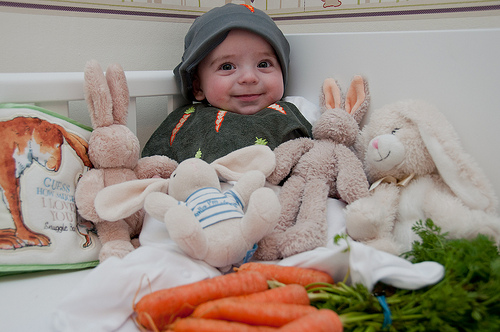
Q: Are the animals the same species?
A: Yes, all the animals are bunnies.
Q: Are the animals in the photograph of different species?
A: No, all the animals are bunnies.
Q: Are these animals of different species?
A: No, all the animals are bunnies.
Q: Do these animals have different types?
A: No, all the animals are bunnies.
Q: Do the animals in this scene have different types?
A: No, all the animals are bunnies.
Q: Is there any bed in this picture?
A: Yes, there is a bed.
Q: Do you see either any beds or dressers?
A: Yes, there is a bed.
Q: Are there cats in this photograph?
A: No, there are no cats.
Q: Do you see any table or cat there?
A: No, there are no cats or tables.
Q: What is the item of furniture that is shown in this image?
A: The piece of furniture is a bed.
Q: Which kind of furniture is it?
A: The piece of furniture is a bed.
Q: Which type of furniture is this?
A: This is a bed.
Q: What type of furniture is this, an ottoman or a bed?
A: This is a bed.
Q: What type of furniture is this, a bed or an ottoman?
A: This is a bed.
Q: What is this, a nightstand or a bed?
A: This is a bed.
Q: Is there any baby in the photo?
A: Yes, there is a baby.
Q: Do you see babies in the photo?
A: Yes, there is a baby.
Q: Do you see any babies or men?
A: Yes, there is a baby.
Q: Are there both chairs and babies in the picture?
A: No, there is a baby but no chairs.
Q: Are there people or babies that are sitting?
A: Yes, the baby is sitting.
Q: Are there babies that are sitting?
A: Yes, there is a baby that is sitting.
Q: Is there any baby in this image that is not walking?
A: Yes, there is a baby that is sitting.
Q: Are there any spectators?
A: No, there are no spectators.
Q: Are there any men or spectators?
A: No, there are no spectators or men.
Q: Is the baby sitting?
A: Yes, the baby is sitting.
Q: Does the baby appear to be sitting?
A: Yes, the baby is sitting.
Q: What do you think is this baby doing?
A: The baby is sitting.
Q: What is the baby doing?
A: The baby is sitting.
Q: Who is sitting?
A: The baby is sitting.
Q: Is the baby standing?
A: No, the baby is sitting.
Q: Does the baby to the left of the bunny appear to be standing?
A: No, the baby is sitting.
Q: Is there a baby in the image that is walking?
A: No, there is a baby but he is sitting.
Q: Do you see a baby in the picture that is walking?
A: No, there is a baby but he is sitting.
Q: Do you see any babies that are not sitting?
A: No, there is a baby but he is sitting.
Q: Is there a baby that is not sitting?
A: No, there is a baby but he is sitting.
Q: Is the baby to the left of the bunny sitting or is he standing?
A: The baby is sitting.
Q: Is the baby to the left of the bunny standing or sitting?
A: The baby is sitting.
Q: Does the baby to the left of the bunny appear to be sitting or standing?
A: The baby is sitting.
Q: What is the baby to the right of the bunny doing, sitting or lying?
A: The baby is sitting.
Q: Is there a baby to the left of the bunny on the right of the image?
A: Yes, there is a baby to the left of the bunny.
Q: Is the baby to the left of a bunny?
A: Yes, the baby is to the left of a bunny.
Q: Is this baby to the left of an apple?
A: No, the baby is to the left of a bunny.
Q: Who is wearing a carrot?
A: The baby is wearing a carrot.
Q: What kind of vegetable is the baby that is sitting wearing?
A: The baby is wearing a carrot.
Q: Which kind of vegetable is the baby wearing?
A: The baby is wearing a carrot.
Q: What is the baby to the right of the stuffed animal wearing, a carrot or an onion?
A: The baby is wearing a carrot.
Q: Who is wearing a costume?
A: The baby is wearing a costume.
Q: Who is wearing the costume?
A: The baby is wearing a costume.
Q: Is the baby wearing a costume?
A: Yes, the baby is wearing a costume.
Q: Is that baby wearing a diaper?
A: No, the baby is wearing a costume.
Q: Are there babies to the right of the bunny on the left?
A: Yes, there is a baby to the right of the bunny.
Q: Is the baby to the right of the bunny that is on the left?
A: Yes, the baby is to the right of the bunny.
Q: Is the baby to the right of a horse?
A: No, the baby is to the right of the bunny.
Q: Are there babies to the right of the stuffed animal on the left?
A: Yes, there is a baby to the right of the stuffed animal.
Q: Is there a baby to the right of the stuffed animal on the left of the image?
A: Yes, there is a baby to the right of the stuffed animal.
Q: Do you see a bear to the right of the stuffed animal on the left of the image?
A: No, there is a baby to the right of the stuffed animal.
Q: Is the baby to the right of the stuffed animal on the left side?
A: Yes, the baby is to the right of the stuffed animal.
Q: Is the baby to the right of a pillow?
A: No, the baby is to the right of the stuffed animal.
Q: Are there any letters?
A: Yes, there are letters.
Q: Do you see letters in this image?
A: Yes, there are letters.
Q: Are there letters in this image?
A: Yes, there are letters.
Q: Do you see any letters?
A: Yes, there are letters.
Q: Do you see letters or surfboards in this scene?
A: Yes, there are letters.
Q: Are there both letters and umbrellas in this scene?
A: No, there are letters but no umbrellas.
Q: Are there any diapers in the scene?
A: No, there are no diapers.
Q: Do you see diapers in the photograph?
A: No, there are no diapers.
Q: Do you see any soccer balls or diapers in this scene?
A: No, there are no diapers or soccer balls.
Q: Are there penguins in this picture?
A: No, there are no penguins.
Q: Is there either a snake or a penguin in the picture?
A: No, there are no penguins or snakes.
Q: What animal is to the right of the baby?
A: The animal is a bunny.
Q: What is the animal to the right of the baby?
A: The animal is a bunny.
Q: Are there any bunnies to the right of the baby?
A: Yes, there is a bunny to the right of the baby.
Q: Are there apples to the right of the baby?
A: No, there is a bunny to the right of the baby.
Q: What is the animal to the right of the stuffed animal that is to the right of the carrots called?
A: The animal is a bunny.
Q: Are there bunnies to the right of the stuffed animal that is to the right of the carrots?
A: Yes, there is a bunny to the right of the stuffed animal.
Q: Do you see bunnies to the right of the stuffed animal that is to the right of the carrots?
A: Yes, there is a bunny to the right of the stuffed animal.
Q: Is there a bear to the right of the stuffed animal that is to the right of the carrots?
A: No, there is a bunny to the right of the stuffed animal.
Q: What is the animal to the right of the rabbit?
A: The animal is a bunny.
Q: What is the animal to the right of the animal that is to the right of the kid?
A: The animal is a bunny.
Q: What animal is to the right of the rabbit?
A: The animal is a bunny.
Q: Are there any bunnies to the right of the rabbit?
A: Yes, there is a bunny to the right of the rabbit.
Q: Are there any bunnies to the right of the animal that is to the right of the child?
A: Yes, there is a bunny to the right of the rabbit.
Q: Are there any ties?
A: Yes, there is a tie.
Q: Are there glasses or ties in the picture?
A: Yes, there is a tie.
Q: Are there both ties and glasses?
A: No, there is a tie but no glasses.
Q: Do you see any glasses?
A: No, there are no glasses.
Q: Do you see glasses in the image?
A: No, there are no glasses.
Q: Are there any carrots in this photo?
A: Yes, there are carrots.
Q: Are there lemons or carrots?
A: Yes, there are carrots.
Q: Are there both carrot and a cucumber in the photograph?
A: No, there are carrots but no cucumbers.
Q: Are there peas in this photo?
A: No, there are no peas.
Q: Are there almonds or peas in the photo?
A: No, there are no peas or almonds.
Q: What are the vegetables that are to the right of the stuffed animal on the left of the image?
A: The vegetables are carrots.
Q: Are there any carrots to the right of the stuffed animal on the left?
A: Yes, there are carrots to the right of the stuffed animal.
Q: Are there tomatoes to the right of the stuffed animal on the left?
A: No, there are carrots to the right of the stuffed animal.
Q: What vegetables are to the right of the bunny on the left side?
A: The vegetables are carrots.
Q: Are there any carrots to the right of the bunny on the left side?
A: Yes, there are carrots to the right of the bunny.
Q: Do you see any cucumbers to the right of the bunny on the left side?
A: No, there are carrots to the right of the bunny.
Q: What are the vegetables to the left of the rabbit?
A: The vegetables are carrots.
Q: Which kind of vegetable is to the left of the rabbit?
A: The vegetables are carrots.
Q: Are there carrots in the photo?
A: Yes, there is a carrot.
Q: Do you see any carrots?
A: Yes, there is a carrot.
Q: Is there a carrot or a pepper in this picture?
A: Yes, there is a carrot.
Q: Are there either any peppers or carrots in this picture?
A: Yes, there is a carrot.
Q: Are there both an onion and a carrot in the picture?
A: No, there is a carrot but no onions.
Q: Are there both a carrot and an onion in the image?
A: No, there is a carrot but no onions.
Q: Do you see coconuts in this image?
A: No, there are no coconuts.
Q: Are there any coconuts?
A: No, there are no coconuts.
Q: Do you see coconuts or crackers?
A: No, there are no coconuts or crackers.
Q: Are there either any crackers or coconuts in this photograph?
A: No, there are no coconuts or crackers.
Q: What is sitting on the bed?
A: The carrot is sitting on the bed.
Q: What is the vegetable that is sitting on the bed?
A: The vegetable is a carrot.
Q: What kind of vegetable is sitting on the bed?
A: The vegetable is a carrot.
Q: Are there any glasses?
A: No, there are no glasses.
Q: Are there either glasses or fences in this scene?
A: No, there are no glasses or fences.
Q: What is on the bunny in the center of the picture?
A: The shirt is on the bunny.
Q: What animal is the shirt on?
A: The shirt is on the bunny.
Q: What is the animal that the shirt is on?
A: The animal is a bunny.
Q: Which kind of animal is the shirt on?
A: The shirt is on the bunny.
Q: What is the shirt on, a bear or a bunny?
A: The shirt is on a bunny.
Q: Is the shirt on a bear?
A: No, the shirt is on the bunny.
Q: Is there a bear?
A: No, there are no bears.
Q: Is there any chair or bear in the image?
A: No, there are no bears or chairs.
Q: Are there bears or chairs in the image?
A: No, there are no bears or chairs.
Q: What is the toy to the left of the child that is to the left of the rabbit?
A: The toy is a stuffed animal.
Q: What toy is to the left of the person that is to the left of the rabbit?
A: The toy is a stuffed animal.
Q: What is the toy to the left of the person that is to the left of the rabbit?
A: The toy is a stuffed animal.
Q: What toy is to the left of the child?
A: The toy is a stuffed animal.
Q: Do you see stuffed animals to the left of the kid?
A: Yes, there is a stuffed animal to the left of the kid.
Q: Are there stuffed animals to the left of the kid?
A: Yes, there is a stuffed animal to the left of the kid.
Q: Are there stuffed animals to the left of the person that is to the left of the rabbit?
A: Yes, there is a stuffed animal to the left of the kid.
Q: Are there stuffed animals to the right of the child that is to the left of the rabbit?
A: No, the stuffed animal is to the left of the child.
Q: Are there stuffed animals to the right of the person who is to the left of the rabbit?
A: No, the stuffed animal is to the left of the child.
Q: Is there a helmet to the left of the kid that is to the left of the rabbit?
A: No, there is a stuffed animal to the left of the child.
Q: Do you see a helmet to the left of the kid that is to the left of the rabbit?
A: No, there is a stuffed animal to the left of the child.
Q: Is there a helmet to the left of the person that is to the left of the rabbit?
A: No, there is a stuffed animal to the left of the child.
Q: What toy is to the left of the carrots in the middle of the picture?
A: The toy is a stuffed animal.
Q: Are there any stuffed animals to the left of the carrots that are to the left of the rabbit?
A: Yes, there is a stuffed animal to the left of the carrots.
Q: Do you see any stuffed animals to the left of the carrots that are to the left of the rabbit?
A: Yes, there is a stuffed animal to the left of the carrots.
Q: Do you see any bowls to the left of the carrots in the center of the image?
A: No, there is a stuffed animal to the left of the carrots.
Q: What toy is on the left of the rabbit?
A: The toy is a stuffed animal.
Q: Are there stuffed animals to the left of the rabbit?
A: Yes, there is a stuffed animal to the left of the rabbit.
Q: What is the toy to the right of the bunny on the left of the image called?
A: The toy is a stuffed animal.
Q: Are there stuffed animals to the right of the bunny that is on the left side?
A: Yes, there is a stuffed animal to the right of the bunny.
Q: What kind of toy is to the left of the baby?
A: The toy is a stuffed animal.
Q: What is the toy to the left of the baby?
A: The toy is a stuffed animal.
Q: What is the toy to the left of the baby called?
A: The toy is a stuffed animal.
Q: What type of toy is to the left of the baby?
A: The toy is a stuffed animal.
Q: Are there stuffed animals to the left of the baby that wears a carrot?
A: Yes, there is a stuffed animal to the left of the baby.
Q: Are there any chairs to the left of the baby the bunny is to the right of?
A: No, there is a stuffed animal to the left of the baby.